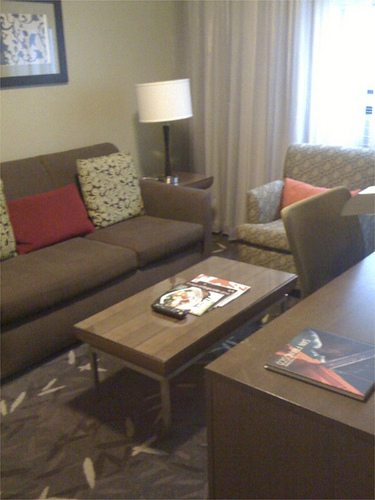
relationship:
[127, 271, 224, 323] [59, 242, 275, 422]
book on table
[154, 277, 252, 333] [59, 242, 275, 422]
books on table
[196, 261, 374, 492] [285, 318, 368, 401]
desk contains book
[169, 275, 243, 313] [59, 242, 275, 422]
magazines sitting on table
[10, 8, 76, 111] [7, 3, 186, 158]
picture hangs on wall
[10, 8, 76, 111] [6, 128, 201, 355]
picture over couch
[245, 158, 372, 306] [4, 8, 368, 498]
chair in living room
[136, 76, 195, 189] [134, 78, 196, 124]
lamp has shade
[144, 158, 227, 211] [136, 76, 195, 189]
end table near lamp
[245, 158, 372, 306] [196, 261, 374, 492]
chair at desk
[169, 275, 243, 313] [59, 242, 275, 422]
magazines on table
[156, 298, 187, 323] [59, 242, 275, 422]
remote on table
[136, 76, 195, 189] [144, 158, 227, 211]
lamp sits on end table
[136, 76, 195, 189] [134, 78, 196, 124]
lamp with shade